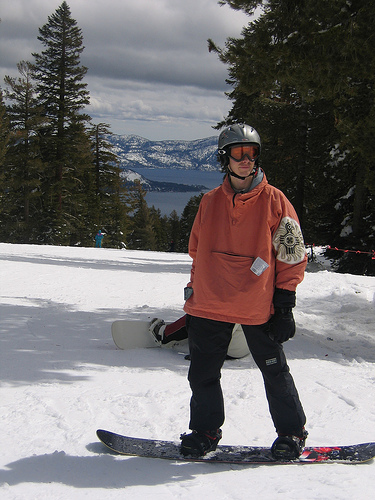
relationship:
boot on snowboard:
[270, 426, 306, 460] [94, 423, 372, 466]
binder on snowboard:
[272, 432, 304, 446] [94, 423, 372, 466]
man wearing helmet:
[179, 122, 321, 459] [218, 123, 264, 151]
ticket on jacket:
[250, 254, 273, 278] [181, 181, 308, 324]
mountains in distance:
[98, 122, 232, 174] [8, 11, 363, 211]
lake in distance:
[129, 164, 230, 219] [8, 11, 363, 211]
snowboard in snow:
[111, 315, 167, 353] [4, 239, 373, 499]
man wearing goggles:
[179, 122, 321, 459] [226, 140, 259, 163]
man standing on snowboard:
[179, 122, 321, 459] [94, 423, 372, 466]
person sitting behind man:
[149, 272, 270, 366] [179, 122, 321, 459]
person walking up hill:
[94, 224, 107, 249] [4, 228, 373, 499]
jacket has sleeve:
[181, 181, 308, 324] [267, 190, 315, 310]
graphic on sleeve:
[270, 216, 308, 267] [267, 190, 315, 310]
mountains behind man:
[98, 122, 232, 174] [179, 122, 321, 459]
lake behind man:
[129, 164, 230, 219] [179, 122, 321, 459]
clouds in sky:
[3, 5, 245, 127] [2, 0, 289, 140]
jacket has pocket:
[181, 181, 308, 324] [211, 246, 263, 297]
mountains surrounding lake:
[98, 122, 232, 174] [129, 164, 230, 219]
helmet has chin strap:
[218, 123, 264, 151] [228, 168, 257, 180]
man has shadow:
[179, 122, 321, 459] [5, 447, 242, 498]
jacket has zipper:
[181, 181, 308, 324] [215, 248, 254, 259]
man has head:
[179, 122, 321, 459] [219, 125, 270, 196]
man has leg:
[179, 122, 321, 459] [243, 310, 321, 441]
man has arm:
[179, 122, 321, 459] [266, 192, 306, 345]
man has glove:
[179, 122, 321, 459] [272, 286, 297, 343]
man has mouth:
[179, 122, 321, 459] [237, 166, 252, 171]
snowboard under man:
[94, 423, 372, 466] [179, 122, 321, 459]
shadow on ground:
[5, 447, 242, 498] [3, 240, 374, 499]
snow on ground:
[4, 239, 373, 499] [3, 240, 374, 499]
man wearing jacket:
[179, 122, 321, 459] [181, 181, 308, 324]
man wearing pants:
[179, 122, 321, 459] [184, 314, 309, 440]